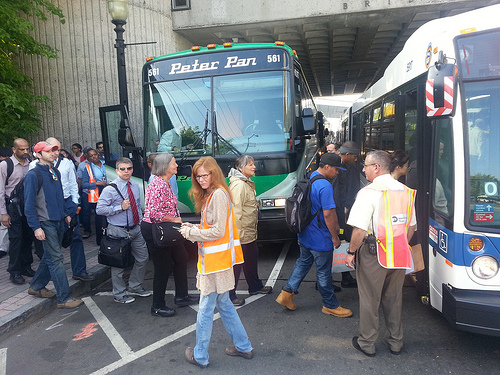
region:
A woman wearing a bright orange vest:
[179, 155, 254, 365]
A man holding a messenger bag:
[96, 158, 152, 302]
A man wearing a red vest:
[347, 149, 414, 356]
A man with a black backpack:
[276, 153, 353, 317]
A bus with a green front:
[139, 40, 325, 241]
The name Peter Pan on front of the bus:
[171, 55, 257, 73]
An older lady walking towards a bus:
[140, 152, 202, 315]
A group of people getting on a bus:
[1, 136, 410, 318]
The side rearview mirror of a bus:
[426, 51, 458, 117]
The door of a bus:
[98, 104, 145, 221]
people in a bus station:
[71, 12, 499, 359]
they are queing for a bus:
[10, 140, 405, 286]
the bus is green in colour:
[136, 27, 297, 150]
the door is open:
[99, 88, 154, 171]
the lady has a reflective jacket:
[190, 180, 244, 279]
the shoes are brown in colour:
[269, 273, 299, 317]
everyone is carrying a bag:
[3, 155, 186, 295]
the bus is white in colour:
[328, 39, 496, 315]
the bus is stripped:
[367, 41, 494, 308]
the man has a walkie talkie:
[336, 195, 386, 322]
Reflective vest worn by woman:
[196, 185, 241, 275]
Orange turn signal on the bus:
[465, 235, 480, 255]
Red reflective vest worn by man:
[370, 185, 420, 265]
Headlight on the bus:
[470, 255, 495, 275]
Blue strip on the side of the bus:
[425, 216, 496, 266]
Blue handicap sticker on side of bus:
[435, 227, 445, 248]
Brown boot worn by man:
[275, 285, 292, 307]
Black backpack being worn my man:
[280, 175, 310, 225]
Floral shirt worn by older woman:
[140, 175, 175, 222]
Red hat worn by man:
[32, 140, 56, 151]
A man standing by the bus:
[341, 147, 429, 357]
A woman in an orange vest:
[177, 154, 257, 365]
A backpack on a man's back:
[285, 169, 330, 229]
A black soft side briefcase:
[94, 182, 134, 268]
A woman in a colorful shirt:
[142, 152, 199, 317]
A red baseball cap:
[32, 140, 60, 152]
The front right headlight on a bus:
[467, 253, 498, 282]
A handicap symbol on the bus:
[436, 229, 450, 254]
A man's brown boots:
[275, 287, 352, 322]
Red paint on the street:
[74, 322, 99, 341]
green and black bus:
[148, 41, 305, 243]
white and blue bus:
[340, 10, 497, 333]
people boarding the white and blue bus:
[10, 140, 425, 315]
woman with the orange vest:
[177, 155, 253, 362]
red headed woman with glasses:
[174, 158, 254, 364]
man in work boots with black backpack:
[280, 151, 354, 316]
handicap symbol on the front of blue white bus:
[435, 230, 450, 252]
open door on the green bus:
[99, 104, 145, 174]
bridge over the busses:
[172, 3, 494, 93]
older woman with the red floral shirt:
[141, 151, 196, 315]